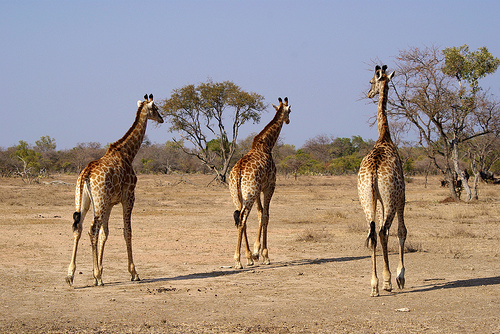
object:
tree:
[156, 76, 270, 185]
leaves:
[228, 92, 230, 94]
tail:
[71, 159, 99, 233]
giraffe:
[64, 92, 166, 288]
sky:
[0, 0, 500, 150]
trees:
[300, 144, 303, 175]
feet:
[63, 235, 79, 289]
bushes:
[2, 137, 494, 183]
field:
[0, 173, 498, 332]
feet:
[122, 232, 141, 282]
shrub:
[0, 138, 46, 187]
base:
[448, 163, 483, 203]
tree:
[361, 41, 498, 201]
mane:
[252, 103, 285, 149]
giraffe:
[225, 95, 292, 269]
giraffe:
[353, 63, 410, 297]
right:
[342, 6, 500, 330]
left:
[0, 0, 159, 334]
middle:
[172, 0, 331, 334]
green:
[158, 81, 271, 124]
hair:
[364, 221, 379, 250]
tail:
[363, 156, 378, 254]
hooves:
[134, 279, 140, 282]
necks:
[112, 110, 147, 163]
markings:
[387, 186, 390, 188]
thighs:
[356, 182, 378, 235]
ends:
[163, 101, 257, 123]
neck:
[252, 111, 286, 153]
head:
[366, 63, 397, 99]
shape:
[155, 75, 270, 124]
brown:
[359, 62, 415, 299]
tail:
[233, 165, 243, 229]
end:
[235, 209, 240, 226]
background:
[9, 8, 500, 174]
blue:
[8, 7, 490, 140]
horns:
[277, 97, 282, 105]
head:
[271, 96, 292, 124]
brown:
[7, 176, 494, 328]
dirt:
[6, 175, 499, 326]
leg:
[120, 198, 141, 282]